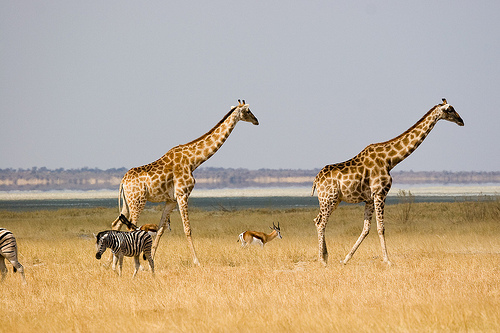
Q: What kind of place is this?
A: It is a field.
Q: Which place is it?
A: It is a field.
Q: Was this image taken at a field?
A: Yes, it was taken in a field.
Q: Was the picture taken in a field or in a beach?
A: It was taken at a field.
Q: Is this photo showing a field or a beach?
A: It is showing a field.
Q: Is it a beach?
A: No, it is a field.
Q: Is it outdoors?
A: Yes, it is outdoors.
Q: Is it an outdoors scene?
A: Yes, it is outdoors.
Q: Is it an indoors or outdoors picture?
A: It is outdoors.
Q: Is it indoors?
A: No, it is outdoors.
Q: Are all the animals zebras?
A: No, there are both giraffes and zebras.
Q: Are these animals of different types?
A: Yes, they are giraffes and zebras.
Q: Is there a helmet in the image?
A: No, there are no helmets.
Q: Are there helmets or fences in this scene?
A: No, there are no helmets or fences.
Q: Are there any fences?
A: No, there are no fences.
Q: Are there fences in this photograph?
A: No, there are no fences.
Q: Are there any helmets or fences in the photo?
A: No, there are no fences or helmets.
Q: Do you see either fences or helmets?
A: No, there are no fences or helmets.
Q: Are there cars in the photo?
A: No, there are no cars.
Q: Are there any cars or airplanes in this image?
A: No, there are no cars or airplanes.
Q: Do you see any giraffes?
A: Yes, there is a giraffe.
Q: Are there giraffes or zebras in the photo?
A: Yes, there is a giraffe.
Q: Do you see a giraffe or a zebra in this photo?
A: Yes, there is a giraffe.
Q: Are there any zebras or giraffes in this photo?
A: Yes, there is a giraffe.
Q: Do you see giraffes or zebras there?
A: Yes, there is a giraffe.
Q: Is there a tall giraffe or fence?
A: Yes, there is a tall giraffe.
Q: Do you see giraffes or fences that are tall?
A: Yes, the giraffe is tall.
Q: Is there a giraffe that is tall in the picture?
A: Yes, there is a tall giraffe.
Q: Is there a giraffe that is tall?
A: Yes, there is a giraffe that is tall.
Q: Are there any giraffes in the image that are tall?
A: Yes, there is a giraffe that is tall.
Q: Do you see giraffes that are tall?
A: Yes, there is a giraffe that is tall.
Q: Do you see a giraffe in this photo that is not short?
A: Yes, there is a tall giraffe.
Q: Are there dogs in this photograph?
A: No, there are no dogs.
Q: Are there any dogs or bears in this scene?
A: No, there are no dogs or bears.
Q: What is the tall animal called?
A: The animal is a giraffe.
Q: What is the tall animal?
A: The animal is a giraffe.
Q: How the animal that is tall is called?
A: The animal is a giraffe.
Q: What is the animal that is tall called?
A: The animal is a giraffe.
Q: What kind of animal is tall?
A: The animal is a giraffe.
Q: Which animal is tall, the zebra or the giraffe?
A: The giraffe is tall.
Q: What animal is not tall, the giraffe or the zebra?
A: The zebra is not tall.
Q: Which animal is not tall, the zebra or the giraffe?
A: The zebra is not tall.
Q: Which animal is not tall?
A: The animal is a zebra.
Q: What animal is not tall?
A: The animal is a zebra.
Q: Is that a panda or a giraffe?
A: That is a giraffe.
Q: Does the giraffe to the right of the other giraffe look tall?
A: Yes, the giraffe is tall.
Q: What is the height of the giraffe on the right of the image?
A: The giraffe is tall.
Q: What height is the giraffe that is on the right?
A: The giraffe is tall.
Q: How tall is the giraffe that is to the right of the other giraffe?
A: The giraffe is tall.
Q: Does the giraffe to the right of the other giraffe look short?
A: No, the giraffe is tall.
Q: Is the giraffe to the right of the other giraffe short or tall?
A: The giraffe is tall.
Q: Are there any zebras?
A: Yes, there is a zebra.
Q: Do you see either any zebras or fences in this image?
A: Yes, there is a zebra.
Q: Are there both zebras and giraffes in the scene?
A: Yes, there are both a zebra and a giraffe.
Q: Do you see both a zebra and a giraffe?
A: Yes, there are both a zebra and a giraffe.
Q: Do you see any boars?
A: No, there are no boars.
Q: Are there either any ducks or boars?
A: No, there are no boars or ducks.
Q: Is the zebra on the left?
A: Yes, the zebra is on the left of the image.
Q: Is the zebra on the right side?
A: No, the zebra is on the left of the image.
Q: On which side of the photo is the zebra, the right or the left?
A: The zebra is on the left of the image.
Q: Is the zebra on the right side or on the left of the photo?
A: The zebra is on the left of the image.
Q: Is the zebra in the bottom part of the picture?
A: Yes, the zebra is in the bottom of the image.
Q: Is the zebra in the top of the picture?
A: No, the zebra is in the bottom of the image.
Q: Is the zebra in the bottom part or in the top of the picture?
A: The zebra is in the bottom of the image.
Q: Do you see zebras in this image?
A: Yes, there is a zebra.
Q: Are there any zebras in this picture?
A: Yes, there is a zebra.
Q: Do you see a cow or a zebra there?
A: Yes, there is a zebra.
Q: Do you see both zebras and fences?
A: No, there is a zebra but no fences.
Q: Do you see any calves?
A: No, there are no calves.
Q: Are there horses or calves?
A: No, there are no calves or horses.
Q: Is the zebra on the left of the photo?
A: Yes, the zebra is on the left of the image.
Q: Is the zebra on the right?
A: No, the zebra is on the left of the image.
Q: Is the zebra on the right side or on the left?
A: The zebra is on the left of the image.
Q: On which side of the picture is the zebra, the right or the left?
A: The zebra is on the left of the image.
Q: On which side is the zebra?
A: The zebra is on the left of the image.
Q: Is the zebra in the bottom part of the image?
A: Yes, the zebra is in the bottom of the image.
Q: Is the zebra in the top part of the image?
A: No, the zebra is in the bottom of the image.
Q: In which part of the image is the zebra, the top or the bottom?
A: The zebra is in the bottom of the image.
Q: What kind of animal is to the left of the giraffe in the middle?
A: The animal is a zebra.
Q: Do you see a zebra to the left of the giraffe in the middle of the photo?
A: Yes, there is a zebra to the left of the giraffe.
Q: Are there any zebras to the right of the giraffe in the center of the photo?
A: No, the zebra is to the left of the giraffe.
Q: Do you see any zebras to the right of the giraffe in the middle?
A: No, the zebra is to the left of the giraffe.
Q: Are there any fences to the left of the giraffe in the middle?
A: No, there is a zebra to the left of the giraffe.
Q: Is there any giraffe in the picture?
A: Yes, there is a giraffe.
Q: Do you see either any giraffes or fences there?
A: Yes, there is a giraffe.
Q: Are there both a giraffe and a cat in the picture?
A: No, there is a giraffe but no cats.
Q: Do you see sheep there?
A: No, there are no sheep.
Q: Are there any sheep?
A: No, there are no sheep.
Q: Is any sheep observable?
A: No, there is no sheep.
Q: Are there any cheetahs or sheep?
A: No, there are no sheep or cheetahs.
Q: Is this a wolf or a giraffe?
A: This is a giraffe.